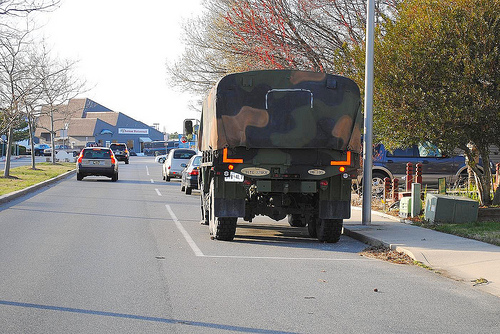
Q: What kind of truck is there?
A: Military.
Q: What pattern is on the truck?
A: Camouflage.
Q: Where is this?
A: Street.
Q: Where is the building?
A: Background.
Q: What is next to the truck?
A: Trees.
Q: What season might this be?
A: Summer.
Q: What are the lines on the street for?
A: Traffic.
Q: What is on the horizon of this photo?
A: A building.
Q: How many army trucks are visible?
A: One.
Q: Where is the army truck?
A: On the road.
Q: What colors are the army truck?
A: Camouflage colors.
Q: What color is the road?
A: Gray.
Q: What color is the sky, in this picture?
A: White.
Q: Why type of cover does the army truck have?
A: A canvas cover.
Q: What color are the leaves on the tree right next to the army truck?
A: Green.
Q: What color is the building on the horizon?
A: Brown.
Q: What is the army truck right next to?
A: A large metal pole.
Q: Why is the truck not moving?
A: It is parked.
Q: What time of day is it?
A: Daytime.